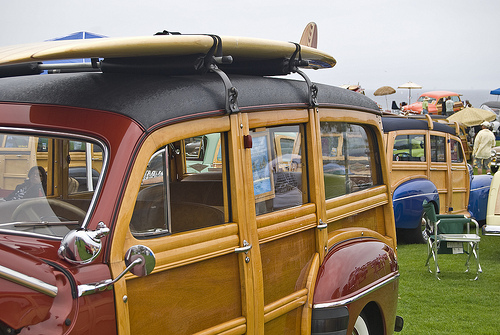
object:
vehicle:
[0, 72, 396, 330]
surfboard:
[0, 22, 338, 73]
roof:
[1, 70, 391, 132]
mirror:
[121, 245, 158, 277]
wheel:
[13, 194, 84, 232]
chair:
[418, 203, 483, 280]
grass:
[391, 223, 499, 334]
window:
[248, 123, 310, 216]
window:
[126, 143, 171, 243]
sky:
[0, 0, 494, 94]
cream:
[3, 23, 337, 65]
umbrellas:
[372, 85, 397, 98]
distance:
[351, 69, 496, 116]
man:
[473, 121, 496, 176]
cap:
[480, 119, 491, 129]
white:
[473, 129, 496, 160]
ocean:
[345, 87, 497, 110]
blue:
[393, 181, 440, 227]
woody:
[380, 115, 493, 241]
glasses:
[27, 171, 43, 178]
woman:
[0, 166, 48, 202]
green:
[422, 200, 471, 257]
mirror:
[58, 230, 101, 266]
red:
[0, 101, 398, 335]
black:
[381, 120, 456, 132]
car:
[406, 92, 464, 113]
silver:
[122, 245, 160, 276]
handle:
[233, 238, 254, 254]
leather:
[1, 74, 383, 128]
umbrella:
[489, 87, 499, 96]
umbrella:
[397, 81, 423, 90]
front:
[1, 72, 110, 332]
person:
[473, 118, 499, 173]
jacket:
[474, 129, 495, 161]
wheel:
[354, 312, 380, 334]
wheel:
[423, 206, 433, 238]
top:
[3, 71, 385, 126]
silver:
[317, 219, 330, 229]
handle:
[317, 218, 329, 232]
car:
[59, 54, 435, 323]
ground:
[392, 221, 499, 334]